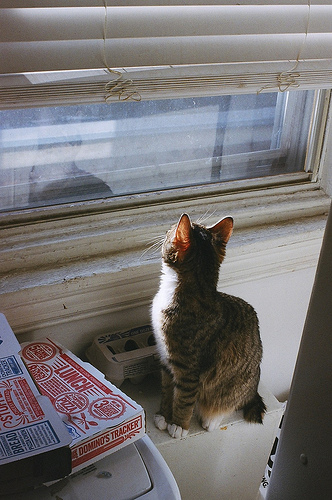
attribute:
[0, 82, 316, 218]
window — reflective, one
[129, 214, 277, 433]
cat — tabby 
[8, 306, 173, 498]
boxes — white 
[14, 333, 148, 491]
boxes — white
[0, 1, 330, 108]
blind — window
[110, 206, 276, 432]
cat — one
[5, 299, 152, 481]
boxes — Domino's Pizza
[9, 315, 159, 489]
boxes — white 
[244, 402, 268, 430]
tail — black 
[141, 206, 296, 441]
cat — one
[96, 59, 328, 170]
window — white 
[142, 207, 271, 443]
cat — brown, black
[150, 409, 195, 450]
feet — white